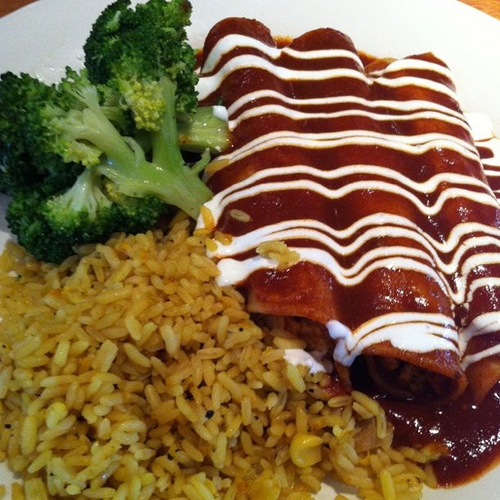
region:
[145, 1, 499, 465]
some Mexican food on the right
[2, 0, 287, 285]
some green broccoli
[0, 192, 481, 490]
a pile of rice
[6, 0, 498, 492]
a white plate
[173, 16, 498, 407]
white sauce dripped on food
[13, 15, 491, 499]
this is a plate of food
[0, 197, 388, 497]
rice on a plate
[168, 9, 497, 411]
tamales on a plate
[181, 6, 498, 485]
red sauce on plate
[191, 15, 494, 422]
white drizzles on tamales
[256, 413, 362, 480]
1 single corn kernal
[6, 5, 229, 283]
broccoli spears on plate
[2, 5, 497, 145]
the plate is white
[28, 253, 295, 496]
the rice is brown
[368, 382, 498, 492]
sauce on the plate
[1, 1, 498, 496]
food on white plate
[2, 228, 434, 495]
pile of cooked rice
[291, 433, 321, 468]
corn kernal on rice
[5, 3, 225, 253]
cut pieces of broccoli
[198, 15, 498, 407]
three enchiladas in sauce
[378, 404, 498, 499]
brown sauce on white plate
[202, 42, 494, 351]
drizzled white sauce on food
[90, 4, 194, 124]
floret of cooked broccoli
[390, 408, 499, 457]
light reflection on sauce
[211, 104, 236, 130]
white sauce on broccoli stem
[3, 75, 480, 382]
food on a plate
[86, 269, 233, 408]
many pieces of food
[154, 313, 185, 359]
one small piece of food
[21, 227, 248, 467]
dark food grouped together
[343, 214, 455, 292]
white sauce on food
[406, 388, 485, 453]
dark sauce on food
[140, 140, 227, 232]
stem of the food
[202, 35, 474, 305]
three pieces of food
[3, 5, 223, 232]
the brocolli next to the rice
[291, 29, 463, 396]
the enchilada in the middle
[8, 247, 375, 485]
the rice is brown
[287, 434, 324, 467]
there is corn in the rice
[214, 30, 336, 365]
the roll on the end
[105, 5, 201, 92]
the top of the brocolli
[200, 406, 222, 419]
the black part of the rice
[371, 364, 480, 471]
the red saice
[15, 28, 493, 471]
the plate is full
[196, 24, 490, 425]
sour cream on meat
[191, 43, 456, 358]
red sauce on meat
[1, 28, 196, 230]
green broccoli on plate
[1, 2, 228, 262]
green colored cooked broccoli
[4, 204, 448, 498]
yellowish cooked rice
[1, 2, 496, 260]
a white colored round plate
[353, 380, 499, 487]
red sauce on a plate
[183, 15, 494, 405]
tamales under a red colored sauce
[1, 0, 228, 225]
several flowerettes of broccoli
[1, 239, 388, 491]
rice with corn kernels in it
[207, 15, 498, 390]
rolled tortillas with sauces topping them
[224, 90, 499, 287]
white decorative glaze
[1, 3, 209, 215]
the broccoli is green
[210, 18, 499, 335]
the sauce is brown